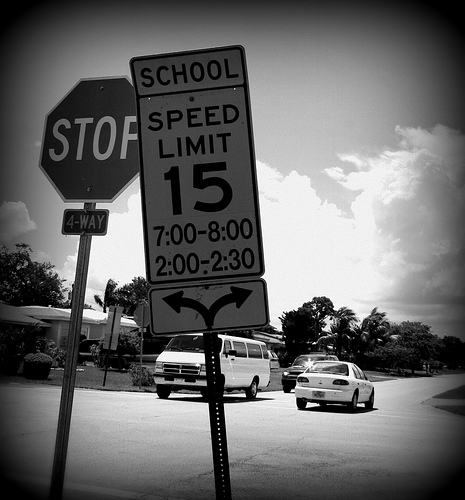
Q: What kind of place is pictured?
A: It is a road.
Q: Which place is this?
A: It is a road.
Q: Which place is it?
A: It is a road.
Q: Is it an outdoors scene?
A: Yes, it is outdoors.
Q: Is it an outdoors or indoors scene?
A: It is outdoors.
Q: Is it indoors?
A: No, it is outdoors.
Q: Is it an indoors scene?
A: No, it is outdoors.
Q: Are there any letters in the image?
A: Yes, there are letters.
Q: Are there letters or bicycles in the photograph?
A: Yes, there are letters.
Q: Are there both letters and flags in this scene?
A: No, there are letters but no flags.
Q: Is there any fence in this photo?
A: No, there are no fences.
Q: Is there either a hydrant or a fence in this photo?
A: No, there are no fences or fire hydrants.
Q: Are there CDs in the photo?
A: No, there are no cds.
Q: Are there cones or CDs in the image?
A: No, there are no CDs or cones.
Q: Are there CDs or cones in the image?
A: No, there are no CDs or cones.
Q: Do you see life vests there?
A: No, there are no life vests.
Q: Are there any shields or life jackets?
A: No, there are no life jackets or shields.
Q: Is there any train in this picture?
A: No, there are no trains.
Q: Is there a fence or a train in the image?
A: No, there are no trains or fences.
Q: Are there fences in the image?
A: No, there are no fences.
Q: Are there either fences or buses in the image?
A: No, there are no fences or buses.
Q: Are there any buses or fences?
A: No, there are no fences or buses.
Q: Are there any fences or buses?
A: No, there are no fences or buses.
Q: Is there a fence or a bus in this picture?
A: No, there are no fences or buses.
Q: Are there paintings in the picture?
A: No, there are no paintings.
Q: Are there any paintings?
A: No, there are no paintings.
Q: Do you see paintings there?
A: No, there are no paintings.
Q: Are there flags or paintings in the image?
A: No, there are no paintings or flags.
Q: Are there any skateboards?
A: No, there are no skateboards.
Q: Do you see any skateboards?
A: No, there are no skateboards.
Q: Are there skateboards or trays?
A: No, there are no skateboards or trays.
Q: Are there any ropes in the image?
A: No, there are no ropes.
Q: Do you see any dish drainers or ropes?
A: No, there are no ropes or dish drainers.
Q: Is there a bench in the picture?
A: No, there are no benches.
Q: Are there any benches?
A: No, there are no benches.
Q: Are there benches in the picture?
A: No, there are no benches.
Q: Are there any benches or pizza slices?
A: No, there are no benches or pizza slices.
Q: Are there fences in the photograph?
A: No, there are no fences.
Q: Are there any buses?
A: No, there are no buses.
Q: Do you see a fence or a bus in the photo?
A: No, there are no buses or fences.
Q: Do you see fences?
A: No, there are no fences.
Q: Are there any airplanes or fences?
A: No, there are no fences or airplanes.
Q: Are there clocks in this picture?
A: No, there are no clocks.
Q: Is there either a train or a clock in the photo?
A: No, there are no clocks or trains.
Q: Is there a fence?
A: No, there are no fences.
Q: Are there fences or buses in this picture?
A: No, there are no fences or buses.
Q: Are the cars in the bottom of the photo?
A: Yes, the cars are in the bottom of the image.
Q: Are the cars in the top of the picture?
A: No, the cars are in the bottom of the image.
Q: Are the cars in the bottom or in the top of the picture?
A: The cars are in the bottom of the image.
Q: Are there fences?
A: No, there are no fences.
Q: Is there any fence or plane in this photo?
A: No, there are no fences or airplanes.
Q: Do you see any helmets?
A: No, there are no helmets.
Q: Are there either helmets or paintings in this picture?
A: No, there are no helmets or paintings.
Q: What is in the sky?
A: The clouds are in the sky.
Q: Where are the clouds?
A: The clouds are in the sky.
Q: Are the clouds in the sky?
A: Yes, the clouds are in the sky.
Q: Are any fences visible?
A: No, there are no fences.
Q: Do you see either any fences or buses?
A: No, there are no fences or buses.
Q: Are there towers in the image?
A: No, there are no towers.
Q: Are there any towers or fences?
A: No, there are no towers or fences.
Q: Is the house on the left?
A: Yes, the house is on the left of the image.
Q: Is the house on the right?
A: No, the house is on the left of the image.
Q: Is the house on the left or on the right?
A: The house is on the left of the image.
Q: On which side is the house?
A: The house is on the left of the image.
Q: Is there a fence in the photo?
A: No, there are no fences.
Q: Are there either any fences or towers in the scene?
A: No, there are no fences or towers.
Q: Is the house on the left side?
A: Yes, the house is on the left of the image.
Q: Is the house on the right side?
A: No, the house is on the left of the image.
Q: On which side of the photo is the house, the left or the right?
A: The house is on the left of the image.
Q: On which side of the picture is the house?
A: The house is on the left of the image.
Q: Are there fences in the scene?
A: No, there are no fences.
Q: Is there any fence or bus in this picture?
A: No, there are no fences or buses.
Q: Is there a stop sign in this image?
A: Yes, there is a stop sign.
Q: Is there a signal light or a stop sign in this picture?
A: Yes, there is a stop sign.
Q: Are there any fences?
A: No, there are no fences.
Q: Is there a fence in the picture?
A: No, there are no fences.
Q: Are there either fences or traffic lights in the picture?
A: No, there are no fences or traffic lights.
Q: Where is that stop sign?
A: The stop sign is at the intersection.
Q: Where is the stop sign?
A: The stop sign is at the intersection.